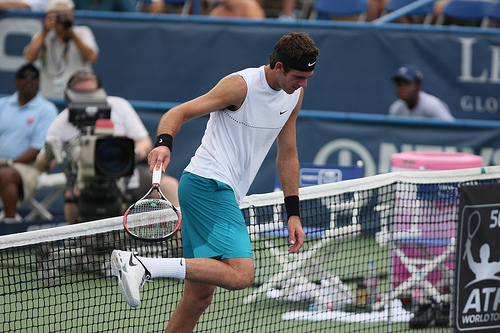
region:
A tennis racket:
[116, 153, 187, 240]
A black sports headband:
[276, 46, 321, 71]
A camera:
[41, 95, 154, 255]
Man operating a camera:
[45, 74, 153, 253]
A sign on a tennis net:
[449, 182, 499, 329]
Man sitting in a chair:
[4, 67, 52, 214]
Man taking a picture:
[27, 3, 99, 97]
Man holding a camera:
[30, 5, 97, 96]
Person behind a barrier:
[383, 59, 453, 131]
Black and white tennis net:
[0, 157, 499, 332]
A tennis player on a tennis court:
[110, 32, 317, 332]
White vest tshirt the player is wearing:
[184, 65, 301, 200]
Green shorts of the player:
[178, 170, 250, 257]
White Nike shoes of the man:
[111, 250, 143, 307]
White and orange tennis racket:
[122, 162, 180, 241]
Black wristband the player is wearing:
[282, 195, 299, 217]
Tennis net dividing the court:
[0, 165, 498, 332]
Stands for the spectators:
[1, 0, 498, 25]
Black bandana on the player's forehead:
[271, 53, 318, 69]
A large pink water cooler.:
[389, 152, 481, 306]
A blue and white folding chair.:
[240, 159, 365, 306]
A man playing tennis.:
[110, 30, 319, 330]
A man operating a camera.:
[35, 70, 179, 277]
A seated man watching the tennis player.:
[0, 63, 65, 227]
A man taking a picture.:
[23, 0, 98, 94]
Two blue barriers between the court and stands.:
[2, 9, 499, 231]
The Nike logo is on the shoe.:
[109, 247, 151, 306]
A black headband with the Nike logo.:
[271, 48, 317, 72]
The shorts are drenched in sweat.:
[177, 169, 254, 260]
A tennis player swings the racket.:
[106, 25, 309, 325]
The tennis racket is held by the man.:
[121, 153, 181, 243]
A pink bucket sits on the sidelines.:
[388, 145, 488, 297]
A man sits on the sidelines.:
[387, 60, 458, 124]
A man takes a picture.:
[24, 0, 109, 100]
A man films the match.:
[62, 83, 137, 234]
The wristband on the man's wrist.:
[281, 193, 303, 216]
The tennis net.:
[312, 181, 450, 321]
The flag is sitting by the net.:
[449, 181, 496, 328]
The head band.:
[270, 29, 319, 93]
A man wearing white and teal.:
[109, 30, 319, 331]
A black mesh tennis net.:
[2, 161, 497, 331]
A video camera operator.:
[35, 68, 153, 279]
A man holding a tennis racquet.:
[107, 30, 321, 331]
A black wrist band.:
[284, 194, 301, 219]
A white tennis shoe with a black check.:
[106, 249, 151, 309]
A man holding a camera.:
[19, 0, 99, 110]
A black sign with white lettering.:
[457, 184, 497, 331]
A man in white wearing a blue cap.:
[382, 63, 452, 122]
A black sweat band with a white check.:
[272, 44, 318, 69]